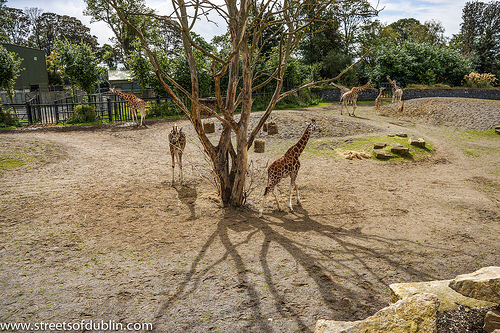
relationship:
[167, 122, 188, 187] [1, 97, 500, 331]
giraffe standing on ground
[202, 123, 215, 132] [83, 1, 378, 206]
food on a tree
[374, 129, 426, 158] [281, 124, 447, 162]
rocks on grass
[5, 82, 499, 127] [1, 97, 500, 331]
fence around ground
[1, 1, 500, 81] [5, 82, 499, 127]
trees beyond fence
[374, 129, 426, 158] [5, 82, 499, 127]
rocks ionside fence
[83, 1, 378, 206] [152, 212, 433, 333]
tree casts a shadow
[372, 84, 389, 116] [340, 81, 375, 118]
baby giraffe by an adult giraffe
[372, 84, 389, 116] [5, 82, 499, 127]
baby giraffe next to fence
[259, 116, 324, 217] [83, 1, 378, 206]
young giraffe by a tree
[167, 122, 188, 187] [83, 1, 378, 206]
young giraffe by tree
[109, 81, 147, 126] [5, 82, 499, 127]
giraffe by fence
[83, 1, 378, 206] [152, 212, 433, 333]
tree has a shadow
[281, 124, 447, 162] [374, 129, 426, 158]
grass with rocks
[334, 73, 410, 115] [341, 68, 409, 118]
giraffes in a group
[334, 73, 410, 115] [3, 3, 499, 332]
giraffes in a zoo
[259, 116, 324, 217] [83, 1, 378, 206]
young giraffe closest to tree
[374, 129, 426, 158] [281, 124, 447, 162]
rocks across grass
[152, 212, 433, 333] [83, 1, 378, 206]
shadow of tree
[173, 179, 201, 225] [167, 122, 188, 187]
shadow of a giraffe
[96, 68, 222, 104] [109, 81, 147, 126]
building beyond giraffe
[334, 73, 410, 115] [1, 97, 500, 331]
giraffes on ground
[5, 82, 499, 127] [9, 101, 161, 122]
fence that metal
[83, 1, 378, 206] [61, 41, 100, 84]
tree has no leaves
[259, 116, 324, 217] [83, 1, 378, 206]
young giraffe near tree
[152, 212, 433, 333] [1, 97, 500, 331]
shadow on ground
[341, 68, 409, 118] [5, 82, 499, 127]
griaffes inside fence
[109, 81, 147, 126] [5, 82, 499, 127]
giraffe next to fence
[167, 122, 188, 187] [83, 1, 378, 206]
giraffe beside tree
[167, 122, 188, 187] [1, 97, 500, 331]
giraffe walking on ground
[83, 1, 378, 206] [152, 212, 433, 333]
tree leaves a shadow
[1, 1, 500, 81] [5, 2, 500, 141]
trees in background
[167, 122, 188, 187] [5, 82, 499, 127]
giraffe inside fence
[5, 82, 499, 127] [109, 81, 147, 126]
fence beside giraffe